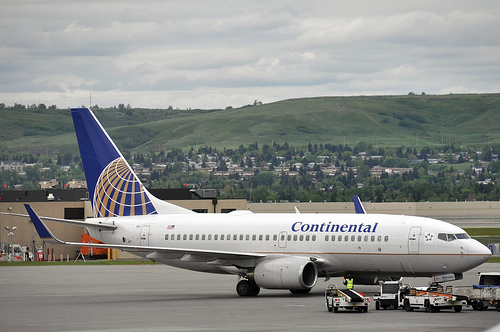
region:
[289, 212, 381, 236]
blue word on plane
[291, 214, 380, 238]
blue word on white plane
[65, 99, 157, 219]
blue tail on white plane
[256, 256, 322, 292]
white engine on plane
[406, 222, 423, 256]
white door on plane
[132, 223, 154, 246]
back door on plane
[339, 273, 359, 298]
person in yellow vest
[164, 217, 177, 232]
flag on white plane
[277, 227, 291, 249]
middle door on plane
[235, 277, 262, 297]
tires on white plane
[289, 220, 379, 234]
Continental logo on white plane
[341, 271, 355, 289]
Person wearing a yellow vest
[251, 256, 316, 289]
Large white jet engine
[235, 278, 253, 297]
Black tire near white jet engine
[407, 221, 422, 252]
Large white door near star logo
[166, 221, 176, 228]
American flag near back white door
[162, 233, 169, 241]
Window on white plane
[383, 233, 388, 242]
Window on white plane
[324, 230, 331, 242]
Window on white plane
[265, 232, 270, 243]
Window on white plane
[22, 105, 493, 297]
a white and blue jet airplane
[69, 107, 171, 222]
the tail of an airplane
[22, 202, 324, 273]
the wing of an airplane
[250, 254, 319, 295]
a jet engine on an airplane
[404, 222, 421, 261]
a door at the front of an airplane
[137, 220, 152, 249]
a door at the rear of an airplane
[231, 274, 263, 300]
a wheel on an airplane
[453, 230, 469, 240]
a window in the cockpit of an airplane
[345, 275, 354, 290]
a yellow vest on a person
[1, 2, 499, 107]
a cloudy sky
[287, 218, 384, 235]
Blue lettering on side of plane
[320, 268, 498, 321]
Ground support crew and vehicles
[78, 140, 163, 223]
Graphic on tail of plane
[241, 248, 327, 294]
Jet engine on wing of plane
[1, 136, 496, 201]
Houses in the distance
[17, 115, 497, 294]
Airplane preparing for takeoff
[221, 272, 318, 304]
Landing gear of airplane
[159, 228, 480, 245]
Windows on airplane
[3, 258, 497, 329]
Tarmac for airplane transport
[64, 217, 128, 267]
Orabge vehicle behind plane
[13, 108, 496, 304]
plane on the tarmac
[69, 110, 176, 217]
blue paint on the tail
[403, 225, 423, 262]
door on the front of the plane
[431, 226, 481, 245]
windows around the cockpit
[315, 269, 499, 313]
vehicles on the tarmac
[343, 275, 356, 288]
neon yellow traffic vest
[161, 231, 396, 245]
row of small windows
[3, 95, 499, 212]
grass on the ground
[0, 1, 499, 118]
sky covered in clouds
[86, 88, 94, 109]
pole in the distance